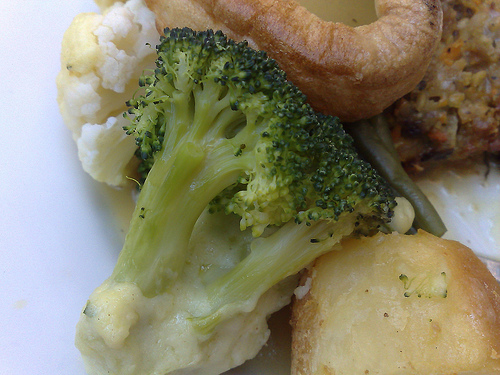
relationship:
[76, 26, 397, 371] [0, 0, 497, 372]
cauliflower on plate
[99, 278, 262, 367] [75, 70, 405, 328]
white sauce on broccoli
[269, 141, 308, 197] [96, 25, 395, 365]
green speckle on broccoli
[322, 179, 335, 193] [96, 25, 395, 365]
speckle on broccoli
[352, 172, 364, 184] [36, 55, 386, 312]
speckle on broccoli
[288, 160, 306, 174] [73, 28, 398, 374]
speckle on broccoli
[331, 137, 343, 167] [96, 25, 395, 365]
speckle on broccoli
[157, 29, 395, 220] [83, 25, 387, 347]
speckle on broccoli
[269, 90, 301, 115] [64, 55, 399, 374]
green speckle on broccoli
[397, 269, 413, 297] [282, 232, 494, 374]
speck on food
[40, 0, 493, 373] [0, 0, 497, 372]
food on plate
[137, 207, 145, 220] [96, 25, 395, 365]
green spot on broccoli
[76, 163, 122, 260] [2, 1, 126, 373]
shadow on plate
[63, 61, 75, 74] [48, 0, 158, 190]
speck on cauliflower